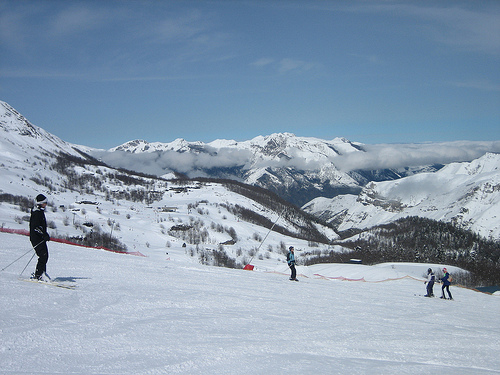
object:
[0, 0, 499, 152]
cloud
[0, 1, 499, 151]
blue sky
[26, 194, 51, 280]
person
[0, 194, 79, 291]
skiing